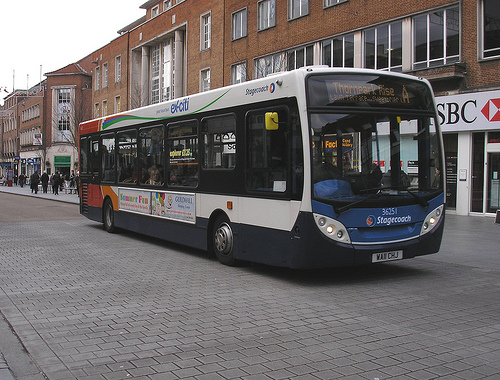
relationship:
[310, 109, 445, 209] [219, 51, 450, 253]
windshield on front of bus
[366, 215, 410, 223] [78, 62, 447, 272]
logo on bus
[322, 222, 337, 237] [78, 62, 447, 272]
headlight on bus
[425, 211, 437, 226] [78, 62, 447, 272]
headlight on bus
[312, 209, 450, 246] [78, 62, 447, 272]
headlights on bus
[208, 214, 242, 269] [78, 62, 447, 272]
wheel of bus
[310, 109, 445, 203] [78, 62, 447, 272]
windshield of bus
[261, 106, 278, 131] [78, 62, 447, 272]
side mirror of bus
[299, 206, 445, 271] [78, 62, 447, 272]
bumper of bus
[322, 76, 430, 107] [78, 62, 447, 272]
sign of bus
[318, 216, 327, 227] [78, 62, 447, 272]
front lights of bus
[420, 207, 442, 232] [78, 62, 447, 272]
light of bus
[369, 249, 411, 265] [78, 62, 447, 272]
license plate of bus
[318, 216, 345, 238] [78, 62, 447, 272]
front lights on bus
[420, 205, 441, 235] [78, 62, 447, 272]
front lights on bus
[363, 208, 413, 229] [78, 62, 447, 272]
writing on front of bus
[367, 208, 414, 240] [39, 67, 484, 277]
writing on front of bus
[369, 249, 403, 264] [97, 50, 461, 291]
license plate on bus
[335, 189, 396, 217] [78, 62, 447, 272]
window wiper on bus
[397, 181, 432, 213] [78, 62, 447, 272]
window wiper on bus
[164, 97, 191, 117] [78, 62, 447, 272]
writing on bus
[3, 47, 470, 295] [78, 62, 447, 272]
windows on bus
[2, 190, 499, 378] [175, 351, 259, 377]
road made of bricks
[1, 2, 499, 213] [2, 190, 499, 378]
buildings next to road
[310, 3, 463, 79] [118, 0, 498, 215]
windows on buildings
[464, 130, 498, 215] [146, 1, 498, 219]
door on building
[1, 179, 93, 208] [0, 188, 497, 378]
ground made of concrete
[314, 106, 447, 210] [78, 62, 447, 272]
window on bus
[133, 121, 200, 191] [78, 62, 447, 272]
window on bus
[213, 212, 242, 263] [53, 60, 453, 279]
wheel on bus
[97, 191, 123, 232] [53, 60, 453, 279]
tire on bus